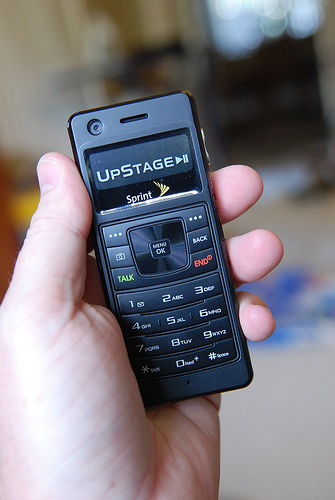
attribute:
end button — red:
[188, 253, 216, 267]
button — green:
[147, 237, 171, 260]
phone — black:
[73, 67, 297, 393]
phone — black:
[71, 89, 254, 393]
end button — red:
[188, 247, 219, 275]